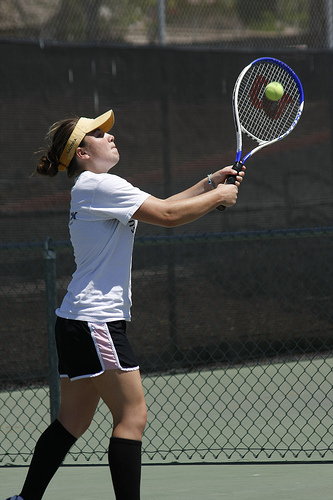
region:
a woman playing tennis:
[15, 46, 305, 496]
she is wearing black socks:
[6, 420, 150, 496]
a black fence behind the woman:
[0, 216, 330, 467]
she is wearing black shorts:
[46, 305, 153, 377]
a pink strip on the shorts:
[86, 319, 118, 370]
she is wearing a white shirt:
[43, 164, 141, 321]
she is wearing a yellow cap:
[61, 99, 116, 174]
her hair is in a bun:
[26, 129, 68, 182]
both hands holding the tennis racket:
[199, 36, 308, 229]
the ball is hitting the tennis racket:
[261, 73, 285, 102]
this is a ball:
[246, 72, 289, 104]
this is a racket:
[225, 47, 313, 203]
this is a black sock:
[104, 433, 142, 494]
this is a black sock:
[1, 419, 64, 492]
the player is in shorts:
[40, 295, 145, 392]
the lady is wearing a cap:
[18, 91, 140, 168]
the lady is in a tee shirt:
[54, 164, 152, 319]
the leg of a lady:
[91, 350, 158, 495]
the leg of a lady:
[3, 339, 92, 487]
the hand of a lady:
[105, 179, 241, 227]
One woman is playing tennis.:
[26, 7, 298, 444]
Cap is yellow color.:
[45, 104, 123, 183]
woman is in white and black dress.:
[31, 208, 132, 367]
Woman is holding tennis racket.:
[206, 52, 281, 205]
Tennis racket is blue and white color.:
[195, 50, 299, 200]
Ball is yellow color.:
[259, 67, 296, 117]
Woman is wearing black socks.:
[17, 410, 145, 499]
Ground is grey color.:
[146, 449, 270, 499]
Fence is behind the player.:
[29, 233, 225, 395]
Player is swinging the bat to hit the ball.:
[87, 53, 303, 267]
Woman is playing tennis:
[4, 50, 308, 498]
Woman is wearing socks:
[17, 417, 146, 497]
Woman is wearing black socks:
[18, 416, 145, 499]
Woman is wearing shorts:
[51, 308, 143, 382]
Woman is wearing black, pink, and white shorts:
[50, 307, 141, 381]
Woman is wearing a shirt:
[54, 169, 155, 325]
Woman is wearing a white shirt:
[49, 167, 155, 326]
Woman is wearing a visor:
[53, 102, 115, 170]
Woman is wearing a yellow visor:
[54, 106, 115, 171]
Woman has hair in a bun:
[31, 113, 92, 179]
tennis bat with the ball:
[227, 50, 314, 230]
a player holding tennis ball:
[48, 69, 302, 254]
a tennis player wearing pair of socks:
[24, 407, 135, 498]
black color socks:
[19, 413, 149, 497]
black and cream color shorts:
[49, 296, 149, 383]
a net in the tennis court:
[152, 238, 330, 453]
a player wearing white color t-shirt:
[71, 171, 152, 327]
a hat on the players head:
[49, 106, 117, 174]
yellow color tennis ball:
[265, 80, 288, 105]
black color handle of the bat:
[215, 160, 241, 217]